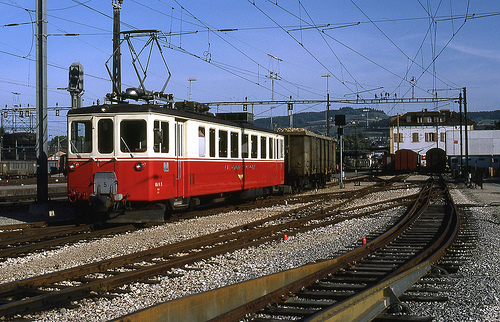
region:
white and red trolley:
[68, 105, 284, 215]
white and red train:
[55, 97, 295, 221]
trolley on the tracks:
[46, 112, 301, 214]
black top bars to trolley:
[100, 24, 166, 113]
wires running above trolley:
[63, 25, 207, 65]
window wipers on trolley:
[110, 133, 138, 163]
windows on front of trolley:
[64, 123, 151, 160]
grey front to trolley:
[85, 170, 121, 195]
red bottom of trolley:
[118, 157, 227, 206]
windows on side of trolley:
[190, 129, 252, 160]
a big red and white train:
[74, 79, 278, 211]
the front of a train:
[50, 102, 167, 199]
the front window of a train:
[61, 121, 102, 158]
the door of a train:
[92, 118, 120, 192]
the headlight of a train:
[115, 158, 146, 170]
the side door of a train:
[162, 118, 197, 182]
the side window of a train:
[202, 126, 242, 150]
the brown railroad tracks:
[80, 233, 141, 295]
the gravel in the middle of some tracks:
[235, 249, 282, 277]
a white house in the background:
[378, 102, 458, 164]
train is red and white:
[59, 114, 284, 209]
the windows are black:
[61, 119, 289, 167]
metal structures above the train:
[1, 2, 498, 122]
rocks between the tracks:
[1, 163, 498, 316]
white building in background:
[385, 117, 480, 154]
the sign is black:
[327, 102, 352, 139]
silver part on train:
[90, 172, 126, 197]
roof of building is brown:
[391, 106, 476, 128]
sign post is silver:
[335, 130, 349, 195]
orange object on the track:
[358, 228, 376, 248]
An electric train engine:
[72, 97, 295, 198]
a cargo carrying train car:
[270, 123, 340, 189]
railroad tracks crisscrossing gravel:
[332, 177, 458, 277]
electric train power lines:
[208, 0, 469, 100]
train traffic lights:
[65, 60, 82, 100]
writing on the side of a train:
[222, 155, 258, 175]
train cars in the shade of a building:
[392, 146, 443, 176]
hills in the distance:
[251, 102, 387, 132]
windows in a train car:
[71, 115, 170, 158]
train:
[82, 83, 287, 213]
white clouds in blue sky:
[332, 14, 414, 82]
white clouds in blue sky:
[249, 38, 328, 76]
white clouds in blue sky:
[208, 19, 272, 59]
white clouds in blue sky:
[281, 14, 351, 65]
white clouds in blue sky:
[279, 8, 326, 35]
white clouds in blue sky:
[352, 10, 438, 55]